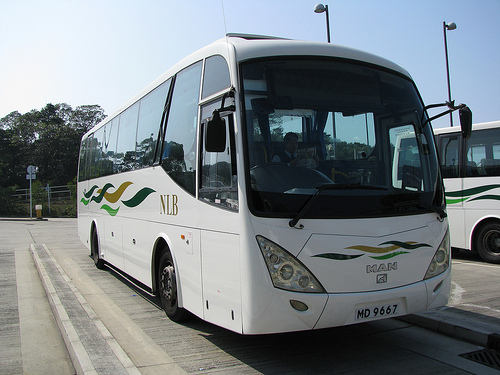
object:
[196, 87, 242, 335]
door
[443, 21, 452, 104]
poles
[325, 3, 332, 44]
poles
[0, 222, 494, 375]
street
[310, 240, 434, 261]
design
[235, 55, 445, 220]
window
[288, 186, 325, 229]
wiper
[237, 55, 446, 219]
windshield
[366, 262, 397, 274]
logo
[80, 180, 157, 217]
decorative design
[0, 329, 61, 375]
pavement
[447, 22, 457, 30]
light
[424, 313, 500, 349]
curb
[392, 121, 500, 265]
bus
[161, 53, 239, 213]
windows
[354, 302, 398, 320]
plate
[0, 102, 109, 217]
trees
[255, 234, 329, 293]
headlight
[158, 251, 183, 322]
front wheel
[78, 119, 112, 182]
window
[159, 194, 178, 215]
logo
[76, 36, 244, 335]
side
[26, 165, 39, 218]
sign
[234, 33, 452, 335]
front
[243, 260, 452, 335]
bottom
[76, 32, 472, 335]
bus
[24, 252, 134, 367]
stripes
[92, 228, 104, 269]
wheel